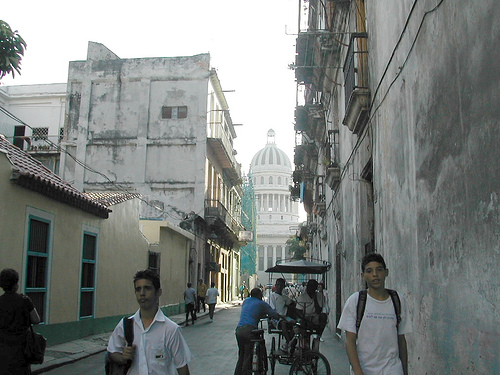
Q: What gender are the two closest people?
A: Male.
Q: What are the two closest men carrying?
A: Backpacks.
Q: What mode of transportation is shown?
A: Bicycle.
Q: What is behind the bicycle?
A: Cart.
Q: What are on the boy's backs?
A: Backpacks.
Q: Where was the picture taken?
A: Alley.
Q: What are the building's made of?
A: Stone.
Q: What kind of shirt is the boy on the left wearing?
A: Polo.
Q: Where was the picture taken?
A: Outside.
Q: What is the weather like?
A: Bright and cloudy.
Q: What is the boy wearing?
A: A backpack.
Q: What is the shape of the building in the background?
A: It is dome shaped.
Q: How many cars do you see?
A: No cars.